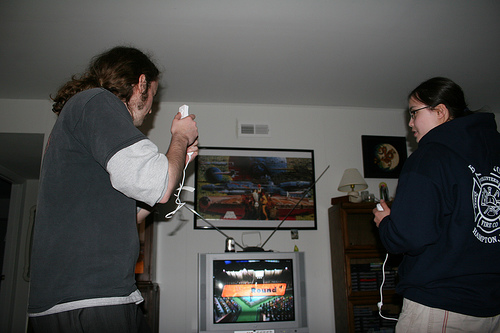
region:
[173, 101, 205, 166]
white video game controller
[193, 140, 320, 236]
black framed painting on wall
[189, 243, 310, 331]
silver television in living room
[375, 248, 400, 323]
white wire to video game controller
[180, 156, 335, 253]
antenna on top of television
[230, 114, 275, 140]
white vent at top of ceiling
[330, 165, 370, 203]
lamp on top shelf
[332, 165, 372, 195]
tan lamp shade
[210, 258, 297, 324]
video game on screen of television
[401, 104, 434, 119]
pair of eye glasses on person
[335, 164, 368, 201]
a lamp on the dresser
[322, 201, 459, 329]
shelves with cds on it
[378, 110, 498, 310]
blue hooded sweatshirt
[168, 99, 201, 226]
white controller and cord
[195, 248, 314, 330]
a silver tv screen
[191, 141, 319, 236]
a picture on the wall above the tv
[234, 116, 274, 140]
a white vent in the wall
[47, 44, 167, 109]
a mans curly hair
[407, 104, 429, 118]
a woman's eyeglasses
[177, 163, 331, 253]
an antenna on a tv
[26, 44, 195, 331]
Man playing a wii game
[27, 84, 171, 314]
A man wearing a white and gray shirt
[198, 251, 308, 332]
A silver television with a game on the screen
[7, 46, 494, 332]
Two people are playing the game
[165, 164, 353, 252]
Antenna on top of the television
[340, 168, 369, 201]
A lamp on the bookcase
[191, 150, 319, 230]
A picture hanging on the wall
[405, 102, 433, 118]
Glasses on the man's face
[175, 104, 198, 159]
A controller in th man's hand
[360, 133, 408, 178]
A small picture frame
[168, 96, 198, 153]
wii control in hand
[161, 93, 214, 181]
wii control in hand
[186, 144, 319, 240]
photo on the wall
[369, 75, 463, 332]
person playing a game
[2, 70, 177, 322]
person playing a game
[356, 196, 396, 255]
wii control in hand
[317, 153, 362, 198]
lamp on the stand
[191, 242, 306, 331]
tv on the stand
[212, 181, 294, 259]
antenna on the tv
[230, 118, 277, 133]
vent on the wall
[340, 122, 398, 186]
photo on the wall